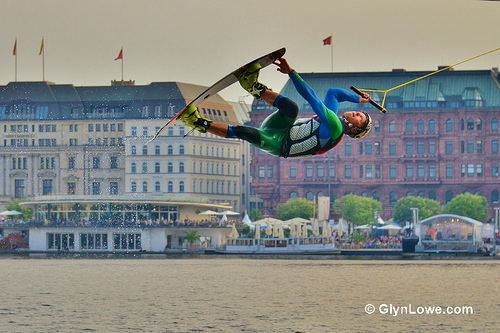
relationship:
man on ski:
[181, 57, 372, 157] [143, 48, 288, 145]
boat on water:
[212, 231, 342, 259] [1, 252, 499, 332]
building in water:
[245, 66, 499, 226] [1, 252, 499, 332]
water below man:
[1, 252, 499, 332] [181, 57, 372, 157]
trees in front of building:
[253, 193, 488, 241] [245, 66, 499, 226]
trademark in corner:
[363, 302, 473, 319] [355, 277, 499, 332]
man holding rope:
[181, 57, 372, 157] [350, 45, 499, 116]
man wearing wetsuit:
[181, 57, 372, 157] [223, 69, 359, 157]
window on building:
[442, 160, 458, 181] [245, 66, 499, 226]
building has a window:
[245, 66, 499, 226] [290, 165, 298, 180]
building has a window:
[245, 66, 499, 226] [445, 161, 454, 179]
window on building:
[442, 160, 458, 181] [0, 78, 253, 224]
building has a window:
[0, 78, 253, 224] [179, 160, 185, 174]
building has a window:
[0, 78, 253, 224] [92, 183, 102, 195]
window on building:
[142, 181, 148, 193] [0, 78, 253, 224]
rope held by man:
[350, 45, 499, 116] [181, 57, 372, 157]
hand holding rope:
[356, 90, 371, 104] [350, 45, 499, 116]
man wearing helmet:
[181, 57, 372, 157] [344, 110, 372, 139]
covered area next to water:
[17, 194, 233, 256] [1, 252, 499, 332]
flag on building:
[322, 33, 334, 72] [245, 66, 499, 226]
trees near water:
[253, 193, 488, 241] [1, 252, 499, 332]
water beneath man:
[1, 252, 499, 332] [181, 57, 372, 157]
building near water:
[0, 78, 253, 224] [1, 252, 499, 332]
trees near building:
[253, 193, 488, 241] [245, 66, 499, 226]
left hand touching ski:
[273, 57, 290, 75] [143, 48, 288, 145]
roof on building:
[1, 80, 241, 125] [0, 78, 253, 224]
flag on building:
[115, 46, 126, 82] [0, 78, 253, 224]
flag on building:
[37, 36, 45, 82] [0, 78, 253, 224]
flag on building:
[12, 36, 18, 83] [0, 78, 253, 224]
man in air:
[181, 57, 372, 157] [2, 4, 142, 318]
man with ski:
[181, 57, 372, 157] [143, 48, 288, 145]